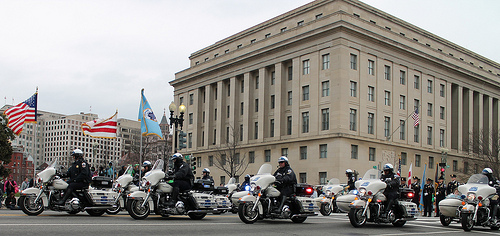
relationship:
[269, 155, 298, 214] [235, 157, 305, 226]
police on motorcycle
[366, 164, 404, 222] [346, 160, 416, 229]
police officer on motorcycle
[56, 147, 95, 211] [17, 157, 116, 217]
officer riding motorcycle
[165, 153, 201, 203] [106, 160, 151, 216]
officer riding motorcylce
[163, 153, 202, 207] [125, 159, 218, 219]
officer on motorcycle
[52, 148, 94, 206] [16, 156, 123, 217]
officer on motorcycle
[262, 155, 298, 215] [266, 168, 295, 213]
police wearing outfit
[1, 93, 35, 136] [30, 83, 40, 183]
flag on pole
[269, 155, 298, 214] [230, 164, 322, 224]
police riding their motorcycle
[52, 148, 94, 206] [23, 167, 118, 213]
officer on motorcycle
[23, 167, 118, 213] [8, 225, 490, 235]
motorcycle on road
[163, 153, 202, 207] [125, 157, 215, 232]
officer on motorcycle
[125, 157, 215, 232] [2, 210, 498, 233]
motorcycle on road